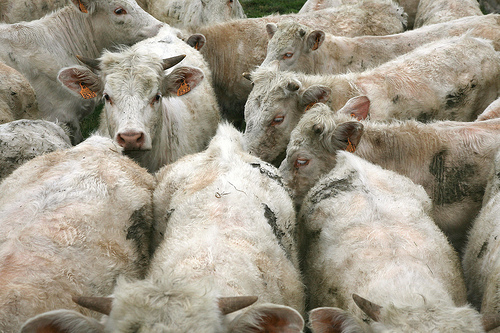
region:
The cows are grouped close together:
[5, 5, 496, 315]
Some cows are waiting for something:
[20, 11, 485, 311]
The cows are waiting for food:
[16, 17, 496, 307]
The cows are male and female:
[16, 17, 454, 329]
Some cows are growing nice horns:
[35, 21, 476, 331]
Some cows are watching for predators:
[37, 21, 497, 326]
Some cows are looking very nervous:
[23, 18, 494, 324]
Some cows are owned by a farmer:
[35, 23, 471, 329]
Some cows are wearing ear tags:
[20, 22, 487, 314]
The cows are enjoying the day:
[32, 19, 487, 314]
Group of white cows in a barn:
[2, 3, 498, 330]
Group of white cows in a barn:
[317, 0, 450, 326]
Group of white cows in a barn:
[15, 0, 192, 320]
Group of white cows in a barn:
[1, 0, 494, 163]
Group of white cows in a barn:
[1, 105, 488, 224]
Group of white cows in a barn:
[236, 4, 471, 254]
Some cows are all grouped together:
[5, 5, 496, 321]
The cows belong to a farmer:
[10, 1, 496, 322]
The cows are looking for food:
[22, 20, 493, 315]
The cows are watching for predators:
[25, 6, 472, 331]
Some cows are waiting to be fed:
[32, 13, 472, 329]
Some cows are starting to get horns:
[26, 11, 481, 309]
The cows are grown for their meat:
[6, 16, 472, 312]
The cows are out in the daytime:
[11, 26, 477, 321]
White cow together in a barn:
[3, 1, 493, 331]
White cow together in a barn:
[0, 0, 245, 328]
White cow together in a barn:
[5, 128, 499, 324]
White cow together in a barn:
[1, 1, 498, 105]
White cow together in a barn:
[1, 100, 475, 292]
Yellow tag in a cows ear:
[338, 135, 357, 164]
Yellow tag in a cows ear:
[175, 80, 187, 91]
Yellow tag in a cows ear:
[77, 82, 89, 104]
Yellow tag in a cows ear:
[304, 37, 326, 48]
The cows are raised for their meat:
[25, 3, 485, 308]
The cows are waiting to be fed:
[15, 23, 465, 326]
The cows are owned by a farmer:
[1, 20, 497, 301]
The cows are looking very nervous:
[20, 11, 496, 312]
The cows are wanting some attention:
[5, 17, 496, 323]